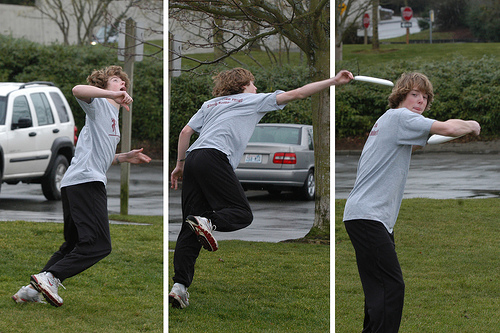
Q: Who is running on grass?
A: Boy with frisbee.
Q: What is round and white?
A: Frisbee.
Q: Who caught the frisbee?
A: Boy in gray.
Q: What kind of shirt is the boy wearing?
A: Gray tee shirt.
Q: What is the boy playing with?
A: Frisbee.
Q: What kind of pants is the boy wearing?
A: Black sweatpants.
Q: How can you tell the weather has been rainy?
A: Parking lot is wet.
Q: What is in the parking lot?
A: White SUV and gray car.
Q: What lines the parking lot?
A: A hedge.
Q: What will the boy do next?
A: Throw the frisbee back.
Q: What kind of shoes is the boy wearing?
A: Running shoes.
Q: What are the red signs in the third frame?
A: Stop signs.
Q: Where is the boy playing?
A: In the grass.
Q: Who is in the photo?
A: The boy.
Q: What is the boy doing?
A: Playing with a frisbee.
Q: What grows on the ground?
A: Grass.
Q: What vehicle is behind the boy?
A: A car.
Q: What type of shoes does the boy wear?
A: Sneakers.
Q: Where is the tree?
A: Behind the boy.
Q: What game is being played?
A: Frisbee.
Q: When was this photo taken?
A: During the daytime.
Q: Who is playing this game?
A: A boy.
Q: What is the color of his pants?
A: Black.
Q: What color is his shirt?
A: Gray.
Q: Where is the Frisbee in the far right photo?
A: In his hands.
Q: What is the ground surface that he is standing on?
A: Grass.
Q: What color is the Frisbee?
A: White.